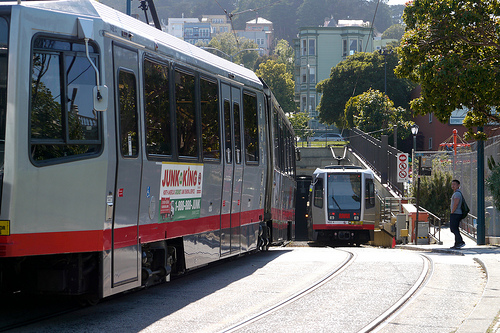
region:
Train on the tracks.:
[279, 137, 434, 246]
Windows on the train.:
[85, 24, 247, 182]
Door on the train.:
[86, 37, 166, 331]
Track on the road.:
[287, 217, 424, 319]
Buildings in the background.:
[297, 10, 396, 143]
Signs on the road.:
[385, 120, 485, 222]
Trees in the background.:
[302, 49, 442, 152]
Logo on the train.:
[143, 153, 229, 236]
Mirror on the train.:
[80, 32, 118, 119]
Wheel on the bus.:
[145, 237, 216, 320]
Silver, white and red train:
[0, 0, 301, 297]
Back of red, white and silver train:
[308, 166, 378, 231]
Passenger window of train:
[135, 47, 226, 162]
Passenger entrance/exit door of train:
[215, 71, 246, 259]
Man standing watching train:
[445, 173, 475, 248]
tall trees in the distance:
[316, 1, 497, 148]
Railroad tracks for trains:
[156, 241, 496, 331]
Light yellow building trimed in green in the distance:
[294, 17, 374, 119]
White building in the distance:
[166, 8, 228, 55]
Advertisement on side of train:
[151, 160, 208, 226]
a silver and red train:
[12, 5, 259, 307]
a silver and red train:
[303, 163, 378, 242]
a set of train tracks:
[227, 229, 432, 331]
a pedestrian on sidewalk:
[445, 175, 470, 248]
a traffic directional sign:
[393, 149, 408, 185]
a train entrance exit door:
[106, 38, 145, 285]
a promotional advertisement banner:
[156, 159, 205, 219]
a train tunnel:
[288, 175, 316, 241]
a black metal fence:
[335, 118, 409, 200]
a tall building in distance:
[294, 25, 376, 127]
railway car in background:
[302, 164, 379, 240]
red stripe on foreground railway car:
[7, 198, 297, 253]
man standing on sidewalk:
[445, 176, 472, 251]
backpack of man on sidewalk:
[461, 190, 466, 223]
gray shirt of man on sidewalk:
[447, 191, 467, 218]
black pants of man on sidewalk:
[449, 215, 471, 242]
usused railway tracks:
[220, 221, 429, 331]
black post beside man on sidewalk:
[472, 130, 488, 245]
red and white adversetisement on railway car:
[152, 161, 206, 199]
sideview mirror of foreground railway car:
[75, 26, 107, 117]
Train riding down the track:
[280, 134, 423, 299]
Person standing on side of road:
[427, 147, 472, 241]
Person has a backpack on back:
[449, 193, 486, 225]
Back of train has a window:
[316, 169, 379, 236]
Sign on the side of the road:
[387, 128, 416, 194]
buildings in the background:
[182, 6, 406, 89]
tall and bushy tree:
[388, 8, 496, 108]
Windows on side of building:
[288, 28, 321, 117]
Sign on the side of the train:
[122, 118, 244, 222]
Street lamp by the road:
[391, 114, 439, 155]